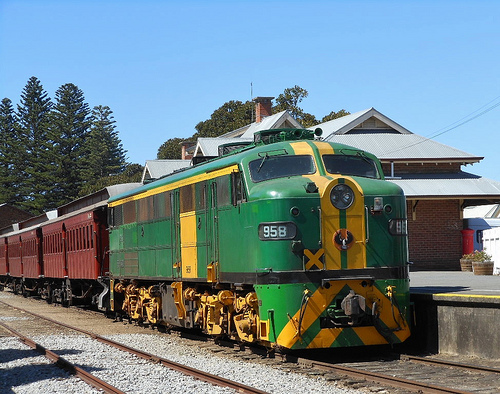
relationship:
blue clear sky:
[400, 7, 489, 71] [159, 1, 335, 72]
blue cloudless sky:
[400, 7, 489, 71] [159, 1, 335, 72]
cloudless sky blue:
[15, 5, 82, 52] [400, 7, 489, 71]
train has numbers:
[242, 147, 408, 354] [256, 225, 293, 240]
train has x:
[242, 147, 408, 354] [301, 249, 326, 270]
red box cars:
[44, 229, 56, 234] [40, 212, 104, 277]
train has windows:
[242, 147, 408, 354] [254, 157, 374, 178]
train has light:
[242, 147, 408, 354] [330, 185, 354, 209]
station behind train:
[409, 145, 463, 273] [242, 147, 408, 354]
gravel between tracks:
[125, 366, 159, 389] [412, 366, 456, 385]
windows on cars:
[23, 239, 37, 254] [40, 212, 104, 277]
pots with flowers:
[458, 262, 495, 273] [464, 251, 491, 261]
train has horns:
[242, 147, 408, 354] [290, 126, 324, 138]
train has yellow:
[242, 147, 408, 354] [324, 210, 338, 229]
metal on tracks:
[183, 368, 197, 375] [412, 366, 456, 385]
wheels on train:
[19, 284, 64, 299] [242, 147, 408, 354]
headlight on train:
[330, 185, 354, 209] [242, 147, 408, 354]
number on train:
[256, 225, 293, 240] [242, 147, 408, 354]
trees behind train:
[3, 98, 87, 182] [242, 147, 408, 354]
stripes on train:
[287, 290, 405, 343] [242, 147, 408, 354]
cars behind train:
[40, 212, 104, 277] [242, 147, 408, 354]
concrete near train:
[412, 272, 465, 282] [242, 147, 408, 354]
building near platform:
[408, 203, 458, 270] [468, 275, 497, 358]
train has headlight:
[242, 147, 408, 354] [286, 207, 305, 217]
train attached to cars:
[242, 147, 408, 354] [40, 212, 104, 277]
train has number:
[242, 147, 408, 354] [394, 222, 407, 235]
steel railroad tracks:
[90, 378, 114, 390] [412, 366, 456, 385]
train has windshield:
[242, 147, 408, 354] [251, 159, 314, 178]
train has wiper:
[242, 147, 408, 354] [257, 152, 268, 169]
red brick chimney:
[426, 210, 441, 224] [256, 97, 273, 115]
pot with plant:
[474, 262, 495, 276] [472, 251, 491, 259]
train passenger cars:
[242, 147, 408, 354] [40, 212, 104, 277]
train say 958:
[242, 147, 408, 354] [263, 224, 290, 238]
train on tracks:
[242, 147, 408, 354] [412, 366, 456, 385]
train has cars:
[242, 147, 408, 354] [40, 212, 104, 277]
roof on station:
[405, 147, 458, 198] [409, 145, 463, 273]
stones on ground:
[129, 362, 153, 384] [202, 352, 227, 373]